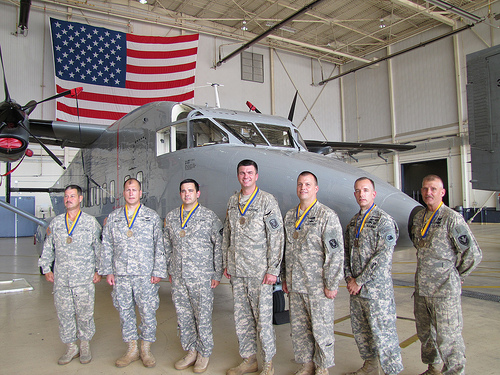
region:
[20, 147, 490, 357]
soldiers standing in a row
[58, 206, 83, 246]
medal around soldier's neck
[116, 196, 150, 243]
medal around soldier's neck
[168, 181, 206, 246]
medal around soldier's neck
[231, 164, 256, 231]
medal around soldier's neck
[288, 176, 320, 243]
medal around soldier's neck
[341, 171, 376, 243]
medal around soldier's neck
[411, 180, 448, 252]
medal around soldier's neck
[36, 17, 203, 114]
american flag hanging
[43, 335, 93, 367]
tan combat boots on soldier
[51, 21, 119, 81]
white stars on a flag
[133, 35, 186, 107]
red and white stripes on a flag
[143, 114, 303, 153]
the windshield of a plane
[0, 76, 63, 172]
a black and red propeller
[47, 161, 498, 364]
seven military men in fatigues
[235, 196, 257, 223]
a blue and gold medal around a man's neck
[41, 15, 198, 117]
an american flag on the wall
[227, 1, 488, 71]
beams on the ceiling of a building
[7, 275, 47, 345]
the floor of a building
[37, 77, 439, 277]
seven men standing in front of a plane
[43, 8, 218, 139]
red, white, and blue american flag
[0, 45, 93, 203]
black and red propellar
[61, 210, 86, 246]
metal with a yellow and blue ribbon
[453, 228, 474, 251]
black and green military patch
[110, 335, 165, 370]
pair of khaki combat boots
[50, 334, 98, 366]
pair of tan combat boots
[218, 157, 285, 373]
tall man in a camouflage military uniform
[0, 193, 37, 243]
blue pair of doors with grey middle bar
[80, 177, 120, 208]
row of passenger windows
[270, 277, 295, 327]
black wheel held by black wheel stop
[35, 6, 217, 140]
American flag hanging in airplane hanger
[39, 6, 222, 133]
American flag with red and white stripes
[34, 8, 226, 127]
American flag with white stars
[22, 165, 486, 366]
Military members with medals around necks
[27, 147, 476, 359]
Military members standing in airplane hanger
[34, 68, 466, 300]
Airplane parked in airplane hanger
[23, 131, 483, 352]
Military men posing for picture with medals around their necks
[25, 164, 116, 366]
Man in military uniform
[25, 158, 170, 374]
Men in combat boots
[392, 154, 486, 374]
Man with military haircut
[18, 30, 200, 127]
American flag on wall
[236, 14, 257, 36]
light on ceiling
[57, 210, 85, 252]
medal on man's neck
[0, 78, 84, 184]
propellor on right side of plane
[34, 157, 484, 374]
men in Army uniforms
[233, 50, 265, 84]
air vent high on wall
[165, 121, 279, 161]
front windscreen of plane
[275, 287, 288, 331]
plane's front wheel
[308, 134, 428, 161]
left wing of plane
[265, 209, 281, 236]
unit patch on man's sleeve